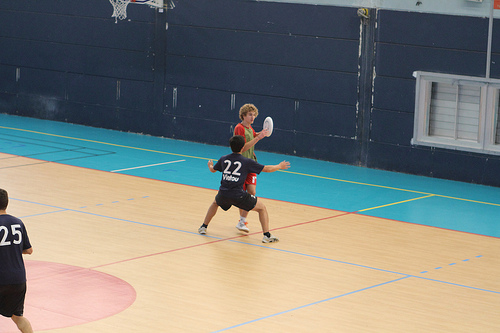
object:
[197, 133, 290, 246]
frisbee player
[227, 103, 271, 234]
frisbee player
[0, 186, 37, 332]
frisbee player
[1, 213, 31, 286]
shirt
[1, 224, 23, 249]
numbers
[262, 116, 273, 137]
frisbee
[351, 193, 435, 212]
line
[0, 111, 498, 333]
floor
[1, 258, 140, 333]
circle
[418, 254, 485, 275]
line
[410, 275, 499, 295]
line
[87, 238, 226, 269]
line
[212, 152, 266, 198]
jersey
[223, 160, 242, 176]
numbers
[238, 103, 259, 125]
head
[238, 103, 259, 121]
hair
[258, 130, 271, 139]
hand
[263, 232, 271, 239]
sock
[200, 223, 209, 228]
sock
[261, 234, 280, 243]
sneaker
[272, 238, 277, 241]
trim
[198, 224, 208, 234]
sneaker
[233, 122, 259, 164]
shirt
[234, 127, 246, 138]
sleeve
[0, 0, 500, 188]
wall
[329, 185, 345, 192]
paint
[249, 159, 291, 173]
arm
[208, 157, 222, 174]
arm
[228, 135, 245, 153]
hair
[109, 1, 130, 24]
net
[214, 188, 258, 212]
shorts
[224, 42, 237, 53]
paint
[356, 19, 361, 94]
marks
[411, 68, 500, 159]
window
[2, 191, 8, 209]
hair